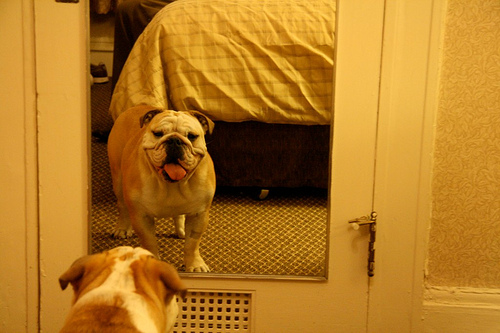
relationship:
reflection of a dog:
[111, 110, 218, 273] [52, 245, 187, 332]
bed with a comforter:
[113, 0, 333, 195] [108, 0, 337, 121]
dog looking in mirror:
[52, 245, 187, 332] [77, 4, 336, 281]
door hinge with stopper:
[349, 210, 378, 274] [348, 219, 359, 230]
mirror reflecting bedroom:
[77, 4, 336, 281] [94, 7, 326, 275]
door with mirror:
[18, 0, 398, 333] [77, 4, 336, 281]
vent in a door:
[173, 284, 251, 332] [18, 0, 398, 333]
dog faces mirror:
[52, 245, 187, 332] [77, 4, 336, 281]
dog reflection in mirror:
[52, 245, 187, 332] [77, 4, 336, 281]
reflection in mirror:
[111, 110, 218, 273] [77, 4, 336, 281]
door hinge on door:
[349, 210, 378, 274] [18, 0, 398, 333]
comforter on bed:
[108, 0, 337, 121] [113, 0, 333, 195]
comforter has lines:
[108, 0, 337, 121] [182, 37, 299, 70]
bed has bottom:
[113, 0, 333, 195] [208, 121, 328, 190]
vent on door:
[173, 284, 251, 332] [18, 0, 398, 333]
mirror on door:
[77, 4, 336, 281] [18, 0, 398, 333]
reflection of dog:
[111, 110, 218, 273] [52, 245, 187, 332]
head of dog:
[62, 247, 187, 320] [52, 245, 187, 332]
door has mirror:
[18, 0, 398, 333] [77, 4, 336, 281]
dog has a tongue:
[52, 245, 187, 332] [163, 164, 190, 180]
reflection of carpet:
[94, 7, 326, 275] [222, 199, 317, 271]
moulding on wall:
[412, 281, 496, 313] [420, 3, 498, 294]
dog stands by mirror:
[52, 245, 187, 332] [77, 4, 336, 281]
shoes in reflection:
[85, 58, 113, 84] [94, 7, 326, 275]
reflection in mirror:
[94, 7, 326, 275] [77, 4, 336, 281]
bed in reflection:
[113, 0, 333, 195] [94, 7, 326, 275]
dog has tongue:
[52, 245, 187, 332] [163, 164, 190, 180]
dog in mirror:
[52, 245, 187, 332] [77, 4, 336, 281]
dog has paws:
[52, 245, 187, 332] [109, 216, 133, 240]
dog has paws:
[52, 245, 187, 332] [179, 250, 214, 272]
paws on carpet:
[109, 216, 133, 240] [222, 199, 317, 271]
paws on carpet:
[179, 250, 214, 272] [222, 199, 317, 271]